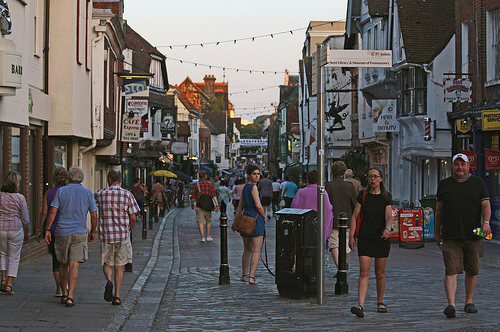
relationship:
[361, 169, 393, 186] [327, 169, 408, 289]
glasses on woman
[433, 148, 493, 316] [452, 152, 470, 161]
man wearing cap